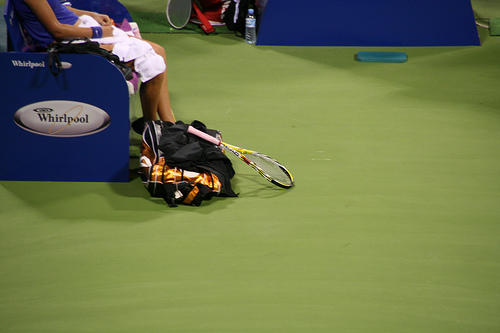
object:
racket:
[185, 125, 295, 190]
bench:
[0, 0, 135, 183]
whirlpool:
[37, 113, 88, 125]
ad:
[19, 104, 106, 135]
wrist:
[90, 26, 102, 38]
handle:
[187, 125, 221, 146]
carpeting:
[6, 61, 490, 324]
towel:
[63, 10, 167, 83]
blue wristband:
[90, 26, 103, 39]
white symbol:
[95, 29, 99, 35]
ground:
[0, 42, 499, 331]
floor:
[1, 1, 497, 331]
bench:
[253, 0, 481, 47]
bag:
[137, 120, 226, 208]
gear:
[159, 119, 240, 198]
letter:
[37, 113, 88, 125]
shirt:
[7, 0, 79, 47]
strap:
[192, 10, 215, 34]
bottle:
[244, 8, 256, 45]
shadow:
[0, 180, 189, 222]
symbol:
[30, 106, 90, 135]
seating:
[3, 12, 130, 183]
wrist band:
[91, 26, 103, 39]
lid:
[248, 9, 255, 14]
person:
[10, 0, 177, 136]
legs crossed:
[111, 29, 176, 125]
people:
[3, 0, 178, 136]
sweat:
[63, 15, 166, 82]